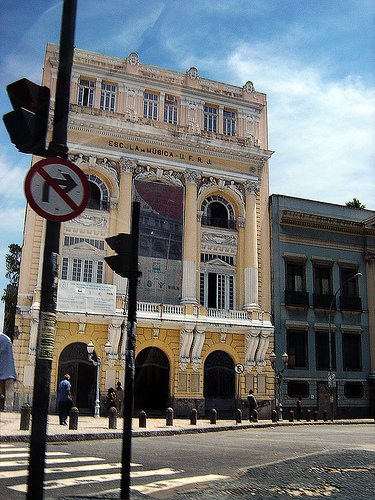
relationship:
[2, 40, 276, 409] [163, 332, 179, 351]
wall has a brick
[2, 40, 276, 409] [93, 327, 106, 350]
wall has a brick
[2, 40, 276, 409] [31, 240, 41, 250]
wall has a brick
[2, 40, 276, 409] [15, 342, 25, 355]
wall has a brick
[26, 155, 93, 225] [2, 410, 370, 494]
sign on street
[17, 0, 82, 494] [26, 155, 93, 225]
pole has a sign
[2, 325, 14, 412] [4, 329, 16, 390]
person has a left shoulder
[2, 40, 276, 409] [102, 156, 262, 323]
building has columns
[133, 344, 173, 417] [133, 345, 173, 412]
doorway has an arch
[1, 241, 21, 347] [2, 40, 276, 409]
tree on side of building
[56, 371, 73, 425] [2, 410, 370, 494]
man walks beside road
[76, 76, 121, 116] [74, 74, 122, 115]
window in a row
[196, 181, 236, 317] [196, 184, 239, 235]
window has an arch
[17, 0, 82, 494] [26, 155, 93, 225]
post has a sign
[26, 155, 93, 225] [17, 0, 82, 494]
sign on pole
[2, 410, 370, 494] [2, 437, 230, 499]
street has a crosswalk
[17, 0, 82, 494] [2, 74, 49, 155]
pole has traffic lights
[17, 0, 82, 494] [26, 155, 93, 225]
pole has an attached sign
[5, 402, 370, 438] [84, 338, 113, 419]
sidewalk has a light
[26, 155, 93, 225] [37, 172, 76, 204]
sign has an arrow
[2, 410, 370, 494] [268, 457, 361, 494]
road has holes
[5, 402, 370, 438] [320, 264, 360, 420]
sidewalk has poles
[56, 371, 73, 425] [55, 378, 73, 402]
man wears blue shirt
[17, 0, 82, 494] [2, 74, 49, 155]
pole has a traffic lights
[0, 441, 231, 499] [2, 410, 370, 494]
lines on street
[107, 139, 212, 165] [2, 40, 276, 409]
name on building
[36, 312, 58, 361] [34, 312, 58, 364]
sign on sign